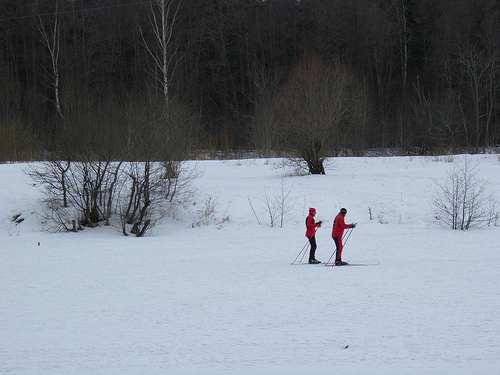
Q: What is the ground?
A: Snow.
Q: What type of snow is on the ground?
A: White snow.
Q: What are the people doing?
A: Skiing.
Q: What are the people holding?
A: Ski poles.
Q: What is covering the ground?
A: Snow.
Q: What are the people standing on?
A: Skis.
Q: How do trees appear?
A: They are bare.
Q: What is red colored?
A: People's clothes.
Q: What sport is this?
A: Skiing.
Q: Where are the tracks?
A: In the snow.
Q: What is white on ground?
A: The snow.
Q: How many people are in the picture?
A: Two.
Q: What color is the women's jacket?
A: Red and black.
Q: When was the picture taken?
A: During the day.